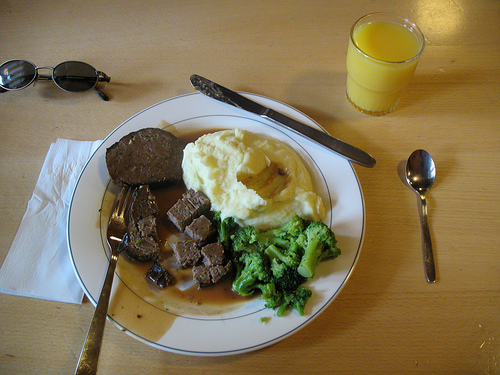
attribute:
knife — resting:
[192, 61, 394, 168]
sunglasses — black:
[0, 53, 119, 106]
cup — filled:
[343, 9, 428, 117]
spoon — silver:
[402, 146, 444, 286]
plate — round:
[80, 90, 384, 370]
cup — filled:
[328, 9, 435, 126]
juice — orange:
[350, 19, 422, 114]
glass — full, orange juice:
[344, 10, 426, 116]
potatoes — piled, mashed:
[179, 126, 329, 232]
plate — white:
[174, 297, 268, 352]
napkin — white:
[0, 137, 106, 304]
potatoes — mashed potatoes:
[171, 124, 328, 228]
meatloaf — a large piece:
[98, 133, 230, 205]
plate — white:
[337, 197, 384, 262]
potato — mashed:
[192, 130, 313, 227]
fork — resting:
[71, 182, 144, 373]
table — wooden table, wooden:
[10, 5, 498, 365]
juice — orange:
[360, 24, 414, 52]